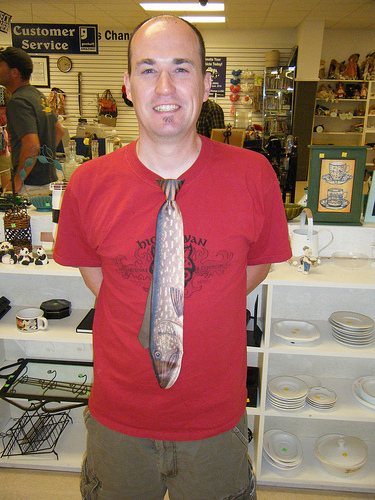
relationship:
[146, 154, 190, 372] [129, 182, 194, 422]
fish on tie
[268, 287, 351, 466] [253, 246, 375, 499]
dishes on shelves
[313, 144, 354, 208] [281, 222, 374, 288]
plaque on shelf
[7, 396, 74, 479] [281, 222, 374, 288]
rack on shelf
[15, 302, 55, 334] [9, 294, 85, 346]
mug on shelf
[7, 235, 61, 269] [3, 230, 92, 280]
ceramics on shelf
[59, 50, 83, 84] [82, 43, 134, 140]
clock on wall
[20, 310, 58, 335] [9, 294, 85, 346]
mug on shelf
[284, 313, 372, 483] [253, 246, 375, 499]
plates on shelf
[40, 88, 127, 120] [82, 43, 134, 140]
bags on wall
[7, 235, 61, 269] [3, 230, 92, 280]
pandas on shelf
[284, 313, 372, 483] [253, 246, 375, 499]
plates on shelves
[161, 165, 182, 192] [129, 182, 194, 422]
clip on tie